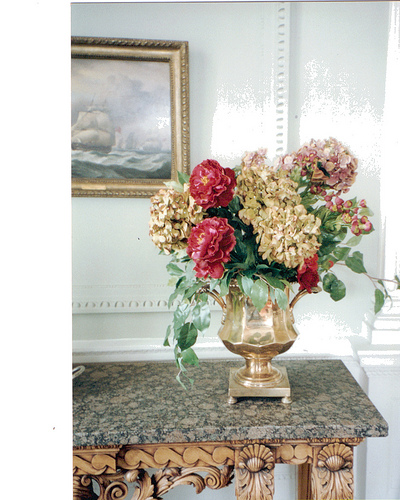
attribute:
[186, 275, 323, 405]
vase — sitting, goldish, gold, golden, present, shiny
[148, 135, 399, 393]
flowers — red, green, rose, gold, present, hanging, white, pink,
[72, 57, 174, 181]
picture — hanging, painted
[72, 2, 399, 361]
wall — white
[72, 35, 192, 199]
frame — golden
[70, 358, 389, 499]
table — marble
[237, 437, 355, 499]
legs — wooden, wood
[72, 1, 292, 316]
moulding — wood